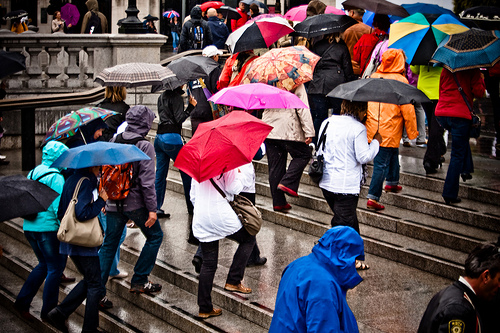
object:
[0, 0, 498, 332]
large crowd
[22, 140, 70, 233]
blue rain jacket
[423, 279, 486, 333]
black jacket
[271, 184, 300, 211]
flat red shoes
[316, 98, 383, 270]
woman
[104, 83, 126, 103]
blonde hair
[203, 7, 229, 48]
man without hair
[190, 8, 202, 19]
dark hood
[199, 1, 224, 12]
an umbrella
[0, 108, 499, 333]
stairs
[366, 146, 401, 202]
jeans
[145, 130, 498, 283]
4 steps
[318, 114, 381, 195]
jacket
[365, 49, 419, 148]
coat is orange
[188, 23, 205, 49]
bag is blue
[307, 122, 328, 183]
black bag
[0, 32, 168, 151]
stand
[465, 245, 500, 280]
grey hair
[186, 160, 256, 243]
pattern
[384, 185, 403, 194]
shoes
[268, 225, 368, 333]
jacket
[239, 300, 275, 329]
stone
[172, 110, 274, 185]
umbrella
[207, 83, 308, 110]
umbrella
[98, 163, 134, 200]
bag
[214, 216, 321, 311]
wet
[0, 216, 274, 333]
stairs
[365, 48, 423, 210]
woman